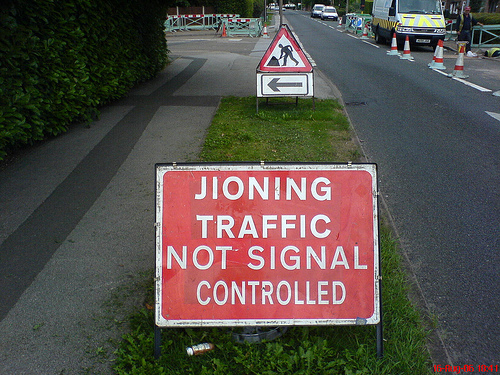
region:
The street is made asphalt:
[383, 66, 450, 181]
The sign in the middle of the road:
[134, 147, 394, 346]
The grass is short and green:
[153, 351, 386, 373]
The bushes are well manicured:
[0, 6, 176, 158]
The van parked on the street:
[367, 0, 452, 55]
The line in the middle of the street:
[426, 59, 490, 100]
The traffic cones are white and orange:
[427, 35, 474, 83]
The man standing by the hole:
[451, 3, 483, 61]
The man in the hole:
[478, 35, 499, 69]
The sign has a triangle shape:
[248, 20, 320, 75]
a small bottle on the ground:
[184, 341, 214, 356]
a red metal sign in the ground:
[152, 161, 382, 359]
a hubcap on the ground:
[226, 325, 289, 345]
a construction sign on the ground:
[255, 23, 315, 111]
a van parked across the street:
[370, 0, 446, 52]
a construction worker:
[442, 5, 485, 57]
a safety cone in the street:
[446, 45, 469, 79]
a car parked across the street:
[319, 5, 339, 20]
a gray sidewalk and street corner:
[0, 50, 337, 374]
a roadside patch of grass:
[109, 94, 436, 374]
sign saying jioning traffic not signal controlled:
[160, 163, 377, 324]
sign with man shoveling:
[257, 9, 315, 71]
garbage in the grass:
[173, 338, 220, 363]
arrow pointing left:
[257, 78, 312, 97]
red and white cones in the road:
[430, 39, 447, 76]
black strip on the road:
[65, 125, 118, 217]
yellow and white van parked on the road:
[370, 2, 450, 44]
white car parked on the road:
[320, 6, 340, 26]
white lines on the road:
[460, 76, 499, 105]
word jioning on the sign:
[192, 169, 346, 210]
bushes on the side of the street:
[0, 0, 165, 155]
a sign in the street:
[150, 160, 375, 320]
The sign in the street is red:
[152, 162, 377, 323]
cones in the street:
[383, 32, 470, 77]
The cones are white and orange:
[390, 31, 466, 81]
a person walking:
[455, 5, 486, 52]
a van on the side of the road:
[372, 2, 444, 47]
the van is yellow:
[369, 0, 454, 33]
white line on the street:
[426, 62, 493, 94]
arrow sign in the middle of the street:
[256, 73, 314, 97]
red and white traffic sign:
[150, 167, 390, 334]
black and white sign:
[247, 70, 325, 116]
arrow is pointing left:
[257, 74, 325, 103]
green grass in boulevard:
[195, 88, 422, 373]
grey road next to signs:
[304, 25, 498, 297]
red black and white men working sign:
[264, 37, 324, 82]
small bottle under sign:
[155, 322, 212, 372]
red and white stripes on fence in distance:
[177, 10, 269, 58]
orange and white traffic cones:
[389, 17, 479, 76]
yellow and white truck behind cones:
[366, 0, 455, 54]